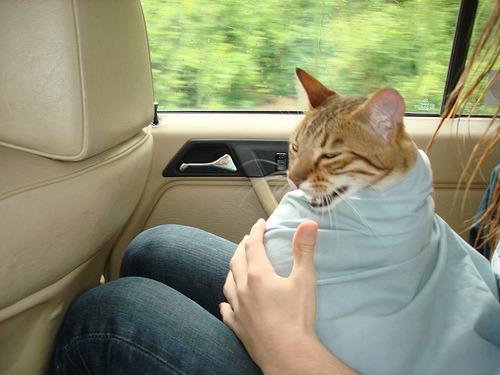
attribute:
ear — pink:
[354, 84, 407, 142]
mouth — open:
[295, 183, 349, 210]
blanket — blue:
[245, 146, 498, 370]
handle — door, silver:
[170, 151, 240, 175]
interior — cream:
[4, 1, 497, 373]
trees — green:
[143, 3, 497, 122]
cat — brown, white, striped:
[226, 58, 497, 371]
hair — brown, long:
[410, 4, 498, 262]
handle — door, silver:
[174, 147, 239, 176]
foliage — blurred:
[142, 4, 498, 113]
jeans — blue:
[43, 216, 293, 371]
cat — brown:
[264, 62, 496, 372]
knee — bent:
[48, 273, 169, 371]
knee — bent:
[118, 223, 220, 299]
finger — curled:
[243, 216, 275, 278]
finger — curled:
[226, 230, 250, 297]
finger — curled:
[219, 265, 246, 313]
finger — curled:
[215, 298, 236, 329]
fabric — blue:
[262, 141, 499, 368]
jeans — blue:
[48, 221, 264, 372]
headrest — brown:
[1, 0, 157, 161]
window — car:
[137, 0, 498, 115]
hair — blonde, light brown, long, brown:
[423, 0, 496, 253]